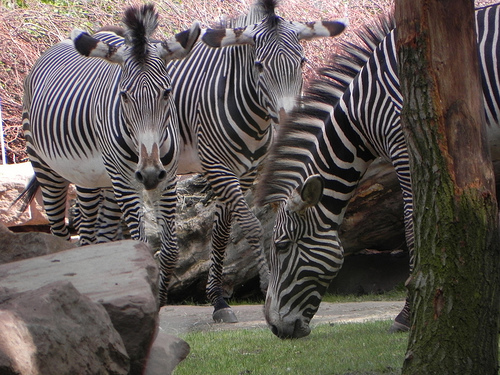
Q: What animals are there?
A: Zebras.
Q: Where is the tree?
A: Right.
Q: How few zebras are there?
A: 3.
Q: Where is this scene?
A: Zoo.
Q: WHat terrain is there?
A: Field.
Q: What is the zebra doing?
A: Grazing.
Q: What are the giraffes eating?
A: Grass.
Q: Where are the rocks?
A: Left.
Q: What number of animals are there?
A: Three.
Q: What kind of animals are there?
A: Zebras.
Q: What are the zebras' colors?
A: Black and white.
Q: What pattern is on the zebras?
A: Stripes.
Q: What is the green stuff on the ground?
A: Grass.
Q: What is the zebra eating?
A: Grass.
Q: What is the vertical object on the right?
A: A tree.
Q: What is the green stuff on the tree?
A: Moss.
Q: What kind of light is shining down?
A: Sunlight.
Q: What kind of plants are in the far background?
A: Bushes.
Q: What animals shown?
A: Zebrass.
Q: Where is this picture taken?
A: A zoo.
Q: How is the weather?
A: Sunny.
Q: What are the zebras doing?
A: Grazing.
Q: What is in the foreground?
A: Tree trunk.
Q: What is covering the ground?
A: Grass.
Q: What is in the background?
A: Trees.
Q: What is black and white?
A: Zebras.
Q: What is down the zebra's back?
A: Mane.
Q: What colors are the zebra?
A: Black and White.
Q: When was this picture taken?
A: Daytime.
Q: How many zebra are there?
A: Three.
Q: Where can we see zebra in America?
A: Zoos.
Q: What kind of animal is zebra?
A: Mammals.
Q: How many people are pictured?
A: None.